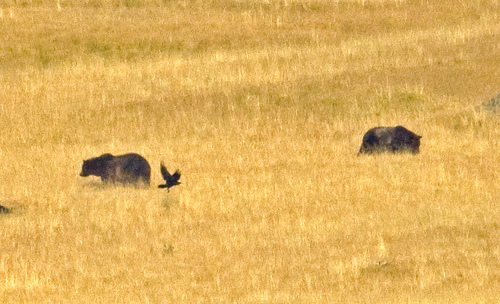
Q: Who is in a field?
A: Bears.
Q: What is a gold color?
A: A field.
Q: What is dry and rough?
A: The field.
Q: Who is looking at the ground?
A: The bear.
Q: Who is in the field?
A: Bears.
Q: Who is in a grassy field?
A: Animals.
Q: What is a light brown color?
A: A grassy field.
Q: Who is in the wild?
A: Creatures.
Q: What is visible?
A: Wildlife.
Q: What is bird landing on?
A: The grass.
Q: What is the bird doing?
A: Flying.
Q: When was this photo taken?
A: Outside, during the daytime.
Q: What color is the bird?
A: Black.